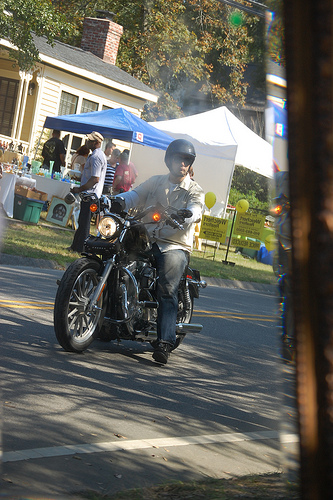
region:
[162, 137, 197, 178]
black motorcycle safety helmet with chin strap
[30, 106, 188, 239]
blue canopy being used as open shelter for yard sale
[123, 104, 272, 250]
white canopy style shelter in yard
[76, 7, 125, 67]
brick chimney on roof top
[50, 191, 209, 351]
black colored motorcycle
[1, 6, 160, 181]
yellow colored home with yellow trim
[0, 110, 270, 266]
yard sale with tables full of items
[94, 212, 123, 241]
turned on motorcycle headlight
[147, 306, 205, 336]
silver motorcycle exhaust system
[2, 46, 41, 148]
open porch on yellow house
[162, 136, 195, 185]
black helmet on the rider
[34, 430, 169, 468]
white line on the pavement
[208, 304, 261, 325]
yellow lines on the pavement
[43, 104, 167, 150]
blue tent on the side of the road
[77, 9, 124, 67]
brick chimney on the roof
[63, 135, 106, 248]
man on the side of the road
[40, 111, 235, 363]
man riding on a motorbike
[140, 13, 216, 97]
tree behind the house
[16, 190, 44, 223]
green bucket under a table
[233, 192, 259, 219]
balloon on a sign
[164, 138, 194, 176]
a black motorcycle helmet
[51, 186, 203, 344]
a black motorcycle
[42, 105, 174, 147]
a blue top to a tent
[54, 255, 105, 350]
a front tire of a motorcycle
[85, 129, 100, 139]
a light colored hat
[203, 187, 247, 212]
a pair of yellow balloons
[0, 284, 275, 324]
yellow street lines painted on road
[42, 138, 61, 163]
a dark short sleeve shirt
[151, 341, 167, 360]
a black leather boot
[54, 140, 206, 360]
a man riding a motorcycle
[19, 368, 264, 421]
The street is made of asphalt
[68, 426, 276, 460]
The line in the street is white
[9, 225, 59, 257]
The grass is short and green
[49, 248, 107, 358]
The front wheel of the motorcycle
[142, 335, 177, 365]
The foot of the man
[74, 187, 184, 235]
The handle bars on the motorcycle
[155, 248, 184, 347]
The man is wearing blue jeans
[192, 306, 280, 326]
The line in the street is yellow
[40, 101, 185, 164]
A canopy tint is the color blue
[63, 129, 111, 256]
A man standing in the grass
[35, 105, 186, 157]
THE TENT IS BLUE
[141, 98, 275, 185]
THE TENT IS WHITE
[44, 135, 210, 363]
THE MAN IS ON THE MOTORCYCLE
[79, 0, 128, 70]
THE CHIMNEY IS ON THE HOUSE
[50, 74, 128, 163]
THE WINDOWS ARE ON THE HOUSE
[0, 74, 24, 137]
THE DOOR IS ON THE HOUSE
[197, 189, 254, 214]
THE BALLOONS ARE YELLOW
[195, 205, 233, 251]
THE SIGN IS YELLOW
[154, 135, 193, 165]
THE MAN IS WEARING A BLACK HELMET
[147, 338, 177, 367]
THE MAN IS WEARING BLACK BOOTS